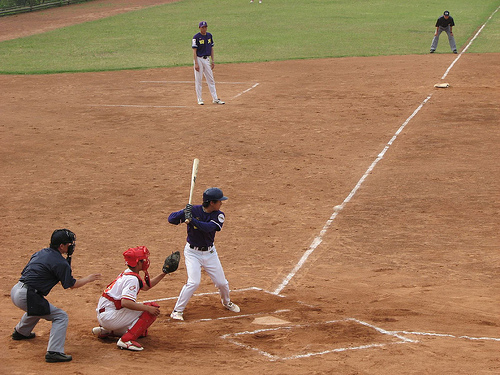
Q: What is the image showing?
A: It is showing a field.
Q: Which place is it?
A: It is a field.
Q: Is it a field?
A: Yes, it is a field.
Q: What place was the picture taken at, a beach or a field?
A: It was taken at a field.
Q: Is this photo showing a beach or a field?
A: It is showing a field.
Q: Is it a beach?
A: No, it is a field.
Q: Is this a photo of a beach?
A: No, the picture is showing a field.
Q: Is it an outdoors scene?
A: Yes, it is outdoors.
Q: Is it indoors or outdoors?
A: It is outdoors.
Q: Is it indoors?
A: No, it is outdoors.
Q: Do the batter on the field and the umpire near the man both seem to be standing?
A: Yes, both the batter and the umpire are standing.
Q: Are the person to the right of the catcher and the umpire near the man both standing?
A: Yes, both the batter and the umpire are standing.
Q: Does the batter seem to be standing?
A: Yes, the batter is standing.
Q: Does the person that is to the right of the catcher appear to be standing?
A: Yes, the batter is standing.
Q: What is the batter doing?
A: The batter is standing.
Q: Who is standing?
A: The batter is standing.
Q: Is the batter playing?
A: Yes, the batter is playing.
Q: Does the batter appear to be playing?
A: Yes, the batter is playing.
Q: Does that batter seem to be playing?
A: Yes, the batter is playing.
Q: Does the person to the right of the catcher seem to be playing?
A: Yes, the batter is playing.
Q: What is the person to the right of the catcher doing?
A: The batter is playing.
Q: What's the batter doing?
A: The batter is playing.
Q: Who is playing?
A: The batter is playing.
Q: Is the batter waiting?
A: No, the batter is playing.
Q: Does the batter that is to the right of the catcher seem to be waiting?
A: No, the batter is playing.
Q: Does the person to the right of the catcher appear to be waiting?
A: No, the batter is playing.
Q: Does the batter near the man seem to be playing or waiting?
A: The batter is playing.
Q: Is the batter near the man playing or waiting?
A: The batter is playing.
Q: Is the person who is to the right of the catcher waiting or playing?
A: The batter is playing.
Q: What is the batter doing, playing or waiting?
A: The batter is playing.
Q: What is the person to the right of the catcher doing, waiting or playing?
A: The batter is playing.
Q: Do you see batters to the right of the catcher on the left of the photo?
A: Yes, there is a batter to the right of the catcher.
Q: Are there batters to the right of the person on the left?
A: Yes, there is a batter to the right of the catcher.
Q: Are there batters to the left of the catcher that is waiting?
A: No, the batter is to the right of the catcher.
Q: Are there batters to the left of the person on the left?
A: No, the batter is to the right of the catcher.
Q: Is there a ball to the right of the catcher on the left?
A: No, there is a batter to the right of the catcher.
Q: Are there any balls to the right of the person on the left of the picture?
A: No, there is a batter to the right of the catcher.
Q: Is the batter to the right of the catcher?
A: Yes, the batter is to the right of the catcher.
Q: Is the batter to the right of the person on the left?
A: Yes, the batter is to the right of the catcher.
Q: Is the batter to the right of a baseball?
A: No, the batter is to the right of the catcher.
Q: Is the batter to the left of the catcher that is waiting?
A: No, the batter is to the right of the catcher.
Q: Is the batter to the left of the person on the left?
A: No, the batter is to the right of the catcher.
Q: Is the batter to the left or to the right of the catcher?
A: The batter is to the right of the catcher.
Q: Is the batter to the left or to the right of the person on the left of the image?
A: The batter is to the right of the catcher.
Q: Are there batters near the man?
A: Yes, there is a batter near the man.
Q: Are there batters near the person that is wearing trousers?
A: Yes, there is a batter near the man.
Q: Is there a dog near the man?
A: No, there is a batter near the man.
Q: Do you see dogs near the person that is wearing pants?
A: No, there is a batter near the man.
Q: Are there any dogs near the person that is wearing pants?
A: No, there is a batter near the man.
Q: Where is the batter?
A: The batter is on the field.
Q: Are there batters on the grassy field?
A: Yes, there is a batter on the field.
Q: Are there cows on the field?
A: No, there is a batter on the field.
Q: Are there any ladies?
A: No, there are no ladies.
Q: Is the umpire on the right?
A: Yes, the umpire is on the right of the image.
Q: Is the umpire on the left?
A: No, the umpire is on the right of the image.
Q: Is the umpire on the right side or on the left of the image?
A: The umpire is on the right of the image.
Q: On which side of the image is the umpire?
A: The umpire is on the right of the image.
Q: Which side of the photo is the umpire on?
A: The umpire is on the right of the image.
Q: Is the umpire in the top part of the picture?
A: Yes, the umpire is in the top of the image.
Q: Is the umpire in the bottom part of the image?
A: No, the umpire is in the top of the image.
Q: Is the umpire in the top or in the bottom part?
A: The umpire is in the top of the image.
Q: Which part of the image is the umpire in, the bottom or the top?
A: The umpire is in the top of the image.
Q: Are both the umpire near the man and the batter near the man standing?
A: Yes, both the umpire and the batter are standing.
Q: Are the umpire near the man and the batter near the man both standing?
A: Yes, both the umpire and the batter are standing.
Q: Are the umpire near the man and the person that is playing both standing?
A: Yes, both the umpire and the batter are standing.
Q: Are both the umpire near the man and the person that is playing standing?
A: Yes, both the umpire and the batter are standing.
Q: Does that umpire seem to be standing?
A: Yes, the umpire is standing.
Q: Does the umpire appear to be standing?
A: Yes, the umpire is standing.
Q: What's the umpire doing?
A: The umpire is standing.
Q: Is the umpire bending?
A: No, the umpire is standing.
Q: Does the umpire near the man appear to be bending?
A: No, the umpire is standing.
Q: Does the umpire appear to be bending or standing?
A: The umpire is standing.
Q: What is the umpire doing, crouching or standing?
A: The umpire is standing.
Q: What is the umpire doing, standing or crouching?
A: The umpire is standing.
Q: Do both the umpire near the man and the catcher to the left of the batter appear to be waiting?
A: Yes, both the umpire and the catcher are waiting.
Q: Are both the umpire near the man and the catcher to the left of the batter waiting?
A: Yes, both the umpire and the catcher are waiting.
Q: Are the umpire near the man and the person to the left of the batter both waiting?
A: Yes, both the umpire and the catcher are waiting.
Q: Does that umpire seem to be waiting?
A: Yes, the umpire is waiting.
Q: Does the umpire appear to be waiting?
A: Yes, the umpire is waiting.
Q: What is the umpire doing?
A: The umpire is waiting.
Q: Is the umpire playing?
A: No, the umpire is waiting.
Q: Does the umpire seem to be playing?
A: No, the umpire is waiting.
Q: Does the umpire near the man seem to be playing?
A: No, the umpire is waiting.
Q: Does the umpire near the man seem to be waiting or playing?
A: The umpire is waiting.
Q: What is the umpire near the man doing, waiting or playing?
A: The umpire is waiting.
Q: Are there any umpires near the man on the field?
A: Yes, there is an umpire near the man.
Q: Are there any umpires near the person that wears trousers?
A: Yes, there is an umpire near the man.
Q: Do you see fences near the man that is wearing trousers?
A: No, there is an umpire near the man.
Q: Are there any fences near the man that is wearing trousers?
A: No, there is an umpire near the man.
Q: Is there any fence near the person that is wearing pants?
A: No, there is an umpire near the man.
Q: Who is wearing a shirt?
A: The umpire is wearing a shirt.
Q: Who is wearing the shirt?
A: The umpire is wearing a shirt.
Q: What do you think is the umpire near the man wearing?
A: The umpire is wearing a shirt.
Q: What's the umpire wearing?
A: The umpire is wearing a shirt.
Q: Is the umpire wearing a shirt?
A: Yes, the umpire is wearing a shirt.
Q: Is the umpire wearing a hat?
A: No, the umpire is wearing a shirt.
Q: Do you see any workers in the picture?
A: No, there are no workers.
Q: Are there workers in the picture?
A: No, there are no workers.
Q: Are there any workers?
A: No, there are no workers.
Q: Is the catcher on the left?
A: Yes, the catcher is on the left of the image.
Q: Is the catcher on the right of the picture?
A: No, the catcher is on the left of the image.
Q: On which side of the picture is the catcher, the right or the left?
A: The catcher is on the left of the image.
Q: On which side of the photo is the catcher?
A: The catcher is on the left of the image.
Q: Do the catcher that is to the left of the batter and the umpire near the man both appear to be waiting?
A: Yes, both the catcher and the umpire are waiting.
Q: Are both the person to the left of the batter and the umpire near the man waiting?
A: Yes, both the catcher and the umpire are waiting.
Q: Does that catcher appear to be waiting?
A: Yes, the catcher is waiting.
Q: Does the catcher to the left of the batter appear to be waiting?
A: Yes, the catcher is waiting.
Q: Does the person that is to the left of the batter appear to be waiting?
A: Yes, the catcher is waiting.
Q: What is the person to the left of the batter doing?
A: The catcher is waiting.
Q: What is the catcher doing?
A: The catcher is waiting.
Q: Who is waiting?
A: The catcher is waiting.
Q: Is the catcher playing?
A: No, the catcher is waiting.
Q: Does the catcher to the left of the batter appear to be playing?
A: No, the catcher is waiting.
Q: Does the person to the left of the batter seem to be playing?
A: No, the catcher is waiting.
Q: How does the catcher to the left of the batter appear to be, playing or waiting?
A: The catcher is waiting.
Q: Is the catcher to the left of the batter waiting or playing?
A: The catcher is waiting.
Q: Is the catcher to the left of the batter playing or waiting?
A: The catcher is waiting.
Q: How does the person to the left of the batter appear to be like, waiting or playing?
A: The catcher is waiting.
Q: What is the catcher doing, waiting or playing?
A: The catcher is waiting.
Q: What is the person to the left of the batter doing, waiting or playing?
A: The catcher is waiting.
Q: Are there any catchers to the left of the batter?
A: Yes, there is a catcher to the left of the batter.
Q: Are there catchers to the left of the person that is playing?
A: Yes, there is a catcher to the left of the batter.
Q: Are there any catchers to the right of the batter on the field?
A: No, the catcher is to the left of the batter.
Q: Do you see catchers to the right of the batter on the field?
A: No, the catcher is to the left of the batter.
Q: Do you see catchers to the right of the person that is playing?
A: No, the catcher is to the left of the batter.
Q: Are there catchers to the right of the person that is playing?
A: No, the catcher is to the left of the batter.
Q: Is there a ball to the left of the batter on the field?
A: No, there is a catcher to the left of the batter.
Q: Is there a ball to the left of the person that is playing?
A: No, there is a catcher to the left of the batter.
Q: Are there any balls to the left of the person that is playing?
A: No, there is a catcher to the left of the batter.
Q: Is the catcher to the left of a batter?
A: Yes, the catcher is to the left of a batter.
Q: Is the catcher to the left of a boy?
A: No, the catcher is to the left of a batter.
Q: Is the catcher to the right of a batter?
A: No, the catcher is to the left of a batter.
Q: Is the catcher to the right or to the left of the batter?
A: The catcher is to the left of the batter.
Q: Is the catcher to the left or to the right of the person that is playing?
A: The catcher is to the left of the batter.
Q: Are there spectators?
A: No, there are no spectators.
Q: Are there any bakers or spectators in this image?
A: No, there are no spectators or bakers.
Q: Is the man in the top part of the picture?
A: Yes, the man is in the top of the image.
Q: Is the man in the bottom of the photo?
A: No, the man is in the top of the image.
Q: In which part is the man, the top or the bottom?
A: The man is in the top of the image.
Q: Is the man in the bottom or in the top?
A: The man is in the top of the image.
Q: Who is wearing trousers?
A: The man is wearing trousers.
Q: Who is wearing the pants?
A: The man is wearing trousers.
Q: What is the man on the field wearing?
A: The man is wearing pants.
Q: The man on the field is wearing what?
A: The man is wearing pants.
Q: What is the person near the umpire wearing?
A: The man is wearing pants.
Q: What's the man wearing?
A: The man is wearing pants.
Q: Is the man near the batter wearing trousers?
A: Yes, the man is wearing trousers.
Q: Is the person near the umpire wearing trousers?
A: Yes, the man is wearing trousers.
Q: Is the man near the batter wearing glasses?
A: No, the man is wearing trousers.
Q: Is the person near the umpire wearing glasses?
A: No, the man is wearing trousers.